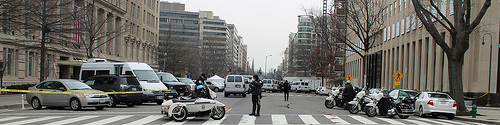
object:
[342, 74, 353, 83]
sign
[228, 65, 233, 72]
traffic light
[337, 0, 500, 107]
building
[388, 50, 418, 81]
ground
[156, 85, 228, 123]
sidecar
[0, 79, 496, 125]
road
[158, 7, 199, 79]
building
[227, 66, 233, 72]
signal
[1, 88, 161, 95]
tape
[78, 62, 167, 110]
van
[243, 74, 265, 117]
officer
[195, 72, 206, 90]
officer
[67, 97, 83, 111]
wheel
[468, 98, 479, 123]
fire hydrant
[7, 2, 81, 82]
tree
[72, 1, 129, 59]
tree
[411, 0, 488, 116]
tree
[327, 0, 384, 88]
tree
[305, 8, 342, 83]
tree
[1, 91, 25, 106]
sidewalk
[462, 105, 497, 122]
sidewalk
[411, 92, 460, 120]
car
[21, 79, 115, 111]
car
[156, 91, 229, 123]
car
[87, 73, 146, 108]
car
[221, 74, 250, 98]
car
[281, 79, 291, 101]
person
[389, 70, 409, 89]
sign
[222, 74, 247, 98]
van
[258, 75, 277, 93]
van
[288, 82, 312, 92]
van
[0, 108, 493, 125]
white lines